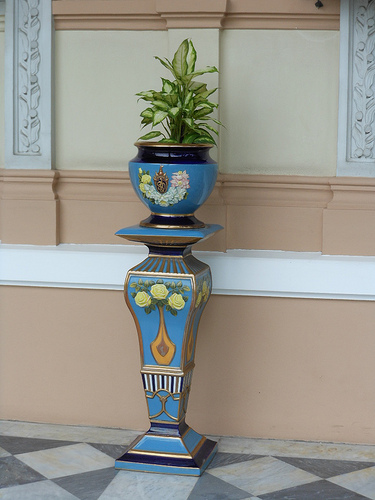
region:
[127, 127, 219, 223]
the vase on the stand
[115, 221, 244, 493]
the stand is decorated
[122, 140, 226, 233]
the vase is decorated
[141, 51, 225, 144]
the plant in the vase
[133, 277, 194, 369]
the flower on the stand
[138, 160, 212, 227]
the flower on the vase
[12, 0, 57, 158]
the molding beside the vase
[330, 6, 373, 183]
the molding beside the vase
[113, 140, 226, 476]
the vase on a stand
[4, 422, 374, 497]
the floor has marble tiles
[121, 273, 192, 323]
the flowers on the stand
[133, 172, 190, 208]
the flowers on the vase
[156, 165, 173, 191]
the crest on the vase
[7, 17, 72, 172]
the gray molding beside the vase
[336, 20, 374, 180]
the gray molding beside the vase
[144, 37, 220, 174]
plant in the pot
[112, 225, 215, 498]
blue color pot stand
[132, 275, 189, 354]
rose design in the pot stand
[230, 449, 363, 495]
white and grey color floor design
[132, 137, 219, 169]
top of the pot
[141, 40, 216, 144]
green color plant in the pot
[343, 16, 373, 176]
some design in the wall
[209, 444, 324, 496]
diamond shapr floor tiles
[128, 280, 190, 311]
three roses in the flower pot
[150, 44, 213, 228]
green plant in the pot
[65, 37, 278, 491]
a decorative vase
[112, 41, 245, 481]
the vase is tall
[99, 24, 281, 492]
the vase is painted in different colors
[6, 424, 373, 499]
the floor is marble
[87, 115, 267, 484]
a vase with gold lining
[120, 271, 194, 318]
flowers painted on a vase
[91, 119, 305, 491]
an enamel vase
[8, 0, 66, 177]
white floral molding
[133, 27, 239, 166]
a green plant in the vase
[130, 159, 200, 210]
a floral design on the vase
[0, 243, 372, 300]
white accent on the wall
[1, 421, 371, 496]
checker pattern on tile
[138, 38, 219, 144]
green plant in the vase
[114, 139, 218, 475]
tall blue vase with design on it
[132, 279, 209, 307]
yellow roses on base of the vase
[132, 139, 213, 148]
gold brim on the vase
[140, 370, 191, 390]
striped design on the base of vase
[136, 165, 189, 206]
decorative flowers on the vase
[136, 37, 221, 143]
green and white leaves on the plant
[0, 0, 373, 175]
decorative plaster design on the wall